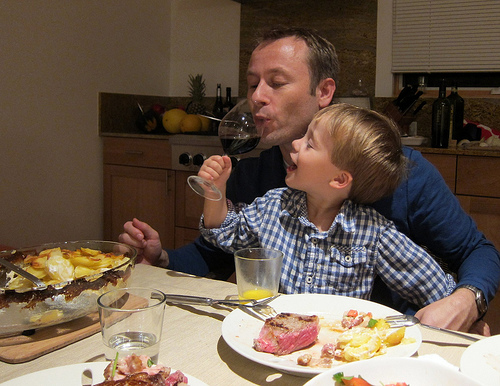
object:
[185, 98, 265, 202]
glass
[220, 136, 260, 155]
red wine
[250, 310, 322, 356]
meat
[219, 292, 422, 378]
plate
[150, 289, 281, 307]
fork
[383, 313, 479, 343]
fork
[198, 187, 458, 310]
shirt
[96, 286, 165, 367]
glass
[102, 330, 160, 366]
water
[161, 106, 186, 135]
fruit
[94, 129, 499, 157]
counter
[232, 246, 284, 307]
glass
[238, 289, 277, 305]
juice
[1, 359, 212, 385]
plate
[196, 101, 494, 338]
child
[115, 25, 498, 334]
father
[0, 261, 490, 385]
table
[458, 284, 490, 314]
watch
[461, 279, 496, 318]
wrist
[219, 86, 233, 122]
bottles